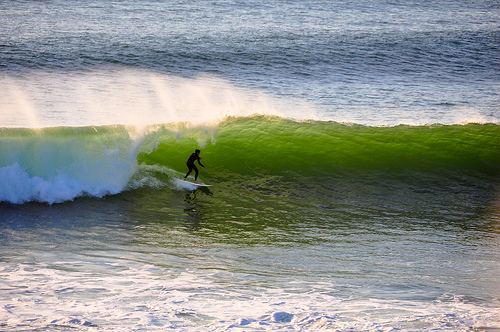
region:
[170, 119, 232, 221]
Man on a surfboard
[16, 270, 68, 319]
Small ripples in the water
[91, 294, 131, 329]
Small ripples in the water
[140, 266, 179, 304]
Small ripples in the water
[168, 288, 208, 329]
Small ripples in the water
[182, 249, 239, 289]
Small ripples in the water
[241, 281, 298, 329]
Small ripples in the water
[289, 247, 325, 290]
Small ripples in the water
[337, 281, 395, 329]
Small ripples in the water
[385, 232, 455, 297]
Small ripples in the water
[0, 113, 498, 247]
bright green, glowing water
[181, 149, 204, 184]
surfer wearing wet suit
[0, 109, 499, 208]
a large green wave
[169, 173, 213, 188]
a white surfboard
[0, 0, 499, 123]
a blue body of water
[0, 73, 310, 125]
water splashing off of wave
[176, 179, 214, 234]
reflection of surfer on water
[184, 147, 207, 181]
man on surfboard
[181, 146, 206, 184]
surfer catching a wave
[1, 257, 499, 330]
sudsy white water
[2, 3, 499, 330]
The wave has a bright green hue.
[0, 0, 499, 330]
The water is splashing.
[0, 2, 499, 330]
The water is rippling.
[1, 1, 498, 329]
The water is wavy.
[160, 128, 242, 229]
The man is on a surfboard.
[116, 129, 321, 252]
The surfboard is in the water.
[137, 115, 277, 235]
The man is wearing a wetsuit.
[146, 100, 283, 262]
The man's wetsuit is black.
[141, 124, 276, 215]
The man's wetsuit has long sleeves.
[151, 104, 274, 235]
The man is barefoot.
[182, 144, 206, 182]
person riding a wave on a surfboard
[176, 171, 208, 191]
surf board the person is riding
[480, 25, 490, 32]
small ripple wave in ocean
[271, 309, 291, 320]
small ripple wave in ocean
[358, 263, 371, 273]
small ripple wave in ocean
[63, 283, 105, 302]
small ripple wave in ocean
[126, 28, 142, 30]
small ripple wave in ocean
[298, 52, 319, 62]
small ripple wave in ocean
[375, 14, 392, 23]
small ripple wave in ocean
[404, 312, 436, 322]
small ripple wave in ocean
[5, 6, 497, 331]
Exterior shot, daytime, probably taken during warmer months.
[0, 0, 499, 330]
Panoramic view of ocean, with lone recreational user.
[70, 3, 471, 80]
Blue ocean, with evidence of swells.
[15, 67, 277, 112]
White spray, from crashing waves.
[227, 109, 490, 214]
Bottle-green wave, headed for surfer.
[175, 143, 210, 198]
Surfer with wave, directly behind.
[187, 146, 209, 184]
Dark figure of man, balancing on board.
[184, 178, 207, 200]
Apparently, white surf board, pointed towards shore.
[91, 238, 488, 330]
Well-churned white-tipped waves, headed for the shoreline.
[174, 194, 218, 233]
Reflection of surfer on water.